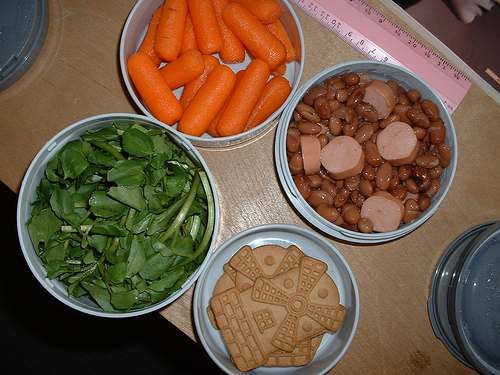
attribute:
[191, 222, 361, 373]
plate — blue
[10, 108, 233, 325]
container — blue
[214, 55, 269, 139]
carrot — orange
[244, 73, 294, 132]
carrot — orange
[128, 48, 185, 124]
carrot — orange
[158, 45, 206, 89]
carrot — orange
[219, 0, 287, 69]
carrot — orange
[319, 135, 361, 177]
meat — brown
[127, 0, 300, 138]
carrots — orange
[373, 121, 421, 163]
meat — brown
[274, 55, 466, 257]
bowl — blue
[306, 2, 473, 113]
ruler — pink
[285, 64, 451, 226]
beans — brown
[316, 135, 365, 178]
meat — brown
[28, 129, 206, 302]
vegetables — leafy, green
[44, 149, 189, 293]
veggie — green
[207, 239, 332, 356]
cookies — golden brown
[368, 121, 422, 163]
meat — brown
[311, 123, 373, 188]
meat — brown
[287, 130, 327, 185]
meat — brown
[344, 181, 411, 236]
meat — brown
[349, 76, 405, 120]
meat — brown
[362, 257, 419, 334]
wood grain — light brown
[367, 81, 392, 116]
meat — brown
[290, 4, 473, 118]
ruler — pink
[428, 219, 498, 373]
container — blue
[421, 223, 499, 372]
lids — blue